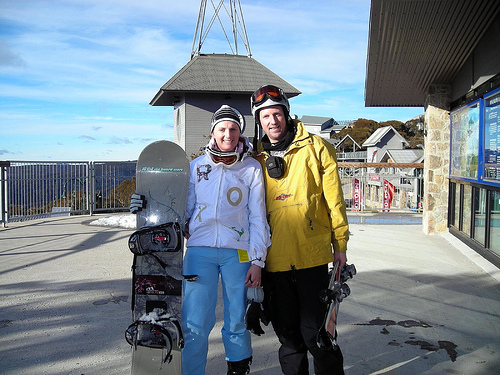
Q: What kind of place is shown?
A: It is a pavement.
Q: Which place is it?
A: It is a pavement.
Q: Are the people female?
A: No, they are both male and female.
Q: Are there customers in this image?
A: No, there are no customers.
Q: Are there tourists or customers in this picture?
A: No, there are no customers or tourists.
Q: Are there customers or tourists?
A: No, there are no customers or tourists.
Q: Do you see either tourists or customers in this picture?
A: No, there are no customers or tourists.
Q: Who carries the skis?
A: The man carries the skis.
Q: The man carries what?
A: The man carries skis.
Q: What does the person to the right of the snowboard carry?
A: The man carries skis.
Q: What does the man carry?
A: The man carries skis.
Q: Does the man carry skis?
A: Yes, the man carries skis.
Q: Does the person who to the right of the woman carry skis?
A: Yes, the man carries skis.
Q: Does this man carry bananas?
A: No, the man carries skis.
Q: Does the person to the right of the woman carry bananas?
A: No, the man carries skis.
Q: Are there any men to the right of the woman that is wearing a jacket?
A: Yes, there is a man to the right of the woman.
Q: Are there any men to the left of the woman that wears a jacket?
A: No, the man is to the right of the woman.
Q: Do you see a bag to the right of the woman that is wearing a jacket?
A: No, there is a man to the right of the woman.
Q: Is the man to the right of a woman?
A: Yes, the man is to the right of a woman.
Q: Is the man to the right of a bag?
A: No, the man is to the right of a woman.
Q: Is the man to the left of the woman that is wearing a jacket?
A: No, the man is to the right of the woman.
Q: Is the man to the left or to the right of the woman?
A: The man is to the right of the woman.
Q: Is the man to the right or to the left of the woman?
A: The man is to the right of the woman.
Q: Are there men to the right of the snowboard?
A: Yes, there is a man to the right of the snowboard.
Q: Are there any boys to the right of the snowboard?
A: No, there is a man to the right of the snowboard.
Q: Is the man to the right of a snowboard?
A: Yes, the man is to the right of a snowboard.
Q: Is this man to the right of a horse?
A: No, the man is to the right of a snowboard.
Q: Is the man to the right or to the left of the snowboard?
A: The man is to the right of the snowboard.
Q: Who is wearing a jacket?
A: The man is wearing a jacket.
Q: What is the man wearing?
A: The man is wearing a jacket.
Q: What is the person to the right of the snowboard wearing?
A: The man is wearing a jacket.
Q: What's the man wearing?
A: The man is wearing a jacket.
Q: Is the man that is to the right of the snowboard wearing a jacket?
A: Yes, the man is wearing a jacket.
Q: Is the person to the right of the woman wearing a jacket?
A: Yes, the man is wearing a jacket.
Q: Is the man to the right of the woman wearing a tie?
A: No, the man is wearing a jacket.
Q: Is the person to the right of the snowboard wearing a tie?
A: No, the man is wearing a jacket.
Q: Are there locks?
A: No, there are no locks.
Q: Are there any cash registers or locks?
A: No, there are no locks or cash registers.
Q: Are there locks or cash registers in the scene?
A: No, there are no locks or cash registers.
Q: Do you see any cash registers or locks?
A: No, there are no locks or cash registers.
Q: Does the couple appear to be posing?
A: Yes, the couple is posing.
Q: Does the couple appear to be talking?
A: No, the couple is posing.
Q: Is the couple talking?
A: No, the couple is posing.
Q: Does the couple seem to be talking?
A: No, the couple is posing.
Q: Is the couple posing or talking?
A: The couple is posing.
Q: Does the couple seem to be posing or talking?
A: The couple is posing.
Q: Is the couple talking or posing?
A: The couple is posing.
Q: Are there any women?
A: Yes, there is a woman.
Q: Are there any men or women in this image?
A: Yes, there is a woman.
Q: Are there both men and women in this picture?
A: Yes, there are both a woman and a man.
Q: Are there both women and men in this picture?
A: Yes, there are both a woman and a man.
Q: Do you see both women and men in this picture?
A: Yes, there are both a woman and a man.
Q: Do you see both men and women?
A: Yes, there are both a woman and a man.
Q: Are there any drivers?
A: No, there are no drivers.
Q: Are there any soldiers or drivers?
A: No, there are no drivers or soldiers.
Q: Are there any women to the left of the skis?
A: Yes, there is a woman to the left of the skis.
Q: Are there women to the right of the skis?
A: No, the woman is to the left of the skis.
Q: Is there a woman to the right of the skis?
A: No, the woman is to the left of the skis.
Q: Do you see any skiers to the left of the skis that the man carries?
A: No, there is a woman to the left of the skis.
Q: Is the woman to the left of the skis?
A: Yes, the woman is to the left of the skis.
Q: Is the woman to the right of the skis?
A: No, the woman is to the left of the skis.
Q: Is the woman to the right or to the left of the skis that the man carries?
A: The woman is to the left of the skis.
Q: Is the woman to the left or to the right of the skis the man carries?
A: The woman is to the left of the skis.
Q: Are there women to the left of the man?
A: Yes, there is a woman to the left of the man.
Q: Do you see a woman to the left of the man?
A: Yes, there is a woman to the left of the man.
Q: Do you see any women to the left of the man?
A: Yes, there is a woman to the left of the man.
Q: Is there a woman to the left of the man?
A: Yes, there is a woman to the left of the man.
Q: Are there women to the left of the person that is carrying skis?
A: Yes, there is a woman to the left of the man.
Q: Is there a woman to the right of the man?
A: No, the woman is to the left of the man.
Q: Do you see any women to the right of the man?
A: No, the woman is to the left of the man.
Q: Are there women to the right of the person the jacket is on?
A: No, the woman is to the left of the man.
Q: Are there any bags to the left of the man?
A: No, there is a woman to the left of the man.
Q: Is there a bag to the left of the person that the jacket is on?
A: No, there is a woman to the left of the man.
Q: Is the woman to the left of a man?
A: Yes, the woman is to the left of a man.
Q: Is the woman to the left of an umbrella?
A: No, the woman is to the left of a man.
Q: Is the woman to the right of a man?
A: No, the woman is to the left of a man.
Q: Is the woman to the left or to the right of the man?
A: The woman is to the left of the man.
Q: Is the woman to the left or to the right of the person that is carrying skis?
A: The woman is to the left of the man.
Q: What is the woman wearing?
A: The woman is wearing a jacket.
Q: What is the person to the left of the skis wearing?
A: The woman is wearing a jacket.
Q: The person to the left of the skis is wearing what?
A: The woman is wearing a jacket.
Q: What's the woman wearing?
A: The woman is wearing a jacket.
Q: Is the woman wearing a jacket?
A: Yes, the woman is wearing a jacket.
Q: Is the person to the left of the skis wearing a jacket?
A: Yes, the woman is wearing a jacket.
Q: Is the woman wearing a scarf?
A: No, the woman is wearing a jacket.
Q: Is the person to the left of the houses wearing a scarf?
A: No, the woman is wearing a jacket.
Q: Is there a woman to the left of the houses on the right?
A: Yes, there is a woman to the left of the houses.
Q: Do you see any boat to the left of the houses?
A: No, there is a woman to the left of the houses.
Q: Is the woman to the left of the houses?
A: Yes, the woman is to the left of the houses.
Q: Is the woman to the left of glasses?
A: No, the woman is to the left of the houses.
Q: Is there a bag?
A: No, there are no bags.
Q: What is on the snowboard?
A: The glove is on the snowboard.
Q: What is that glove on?
A: The glove is on the snowboard.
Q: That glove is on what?
A: The glove is on the snowboard.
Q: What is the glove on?
A: The glove is on the snowboard.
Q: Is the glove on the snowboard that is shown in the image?
A: Yes, the glove is on the snowboard.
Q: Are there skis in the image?
A: Yes, there are skis.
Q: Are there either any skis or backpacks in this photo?
A: Yes, there are skis.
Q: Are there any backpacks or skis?
A: Yes, there are skis.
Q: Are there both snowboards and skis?
A: Yes, there are both skis and a snowboard.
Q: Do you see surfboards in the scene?
A: No, there are no surfboards.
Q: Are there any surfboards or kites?
A: No, there are no surfboards or kites.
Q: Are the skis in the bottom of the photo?
A: Yes, the skis are in the bottom of the image.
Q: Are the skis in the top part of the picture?
A: No, the skis are in the bottom of the image.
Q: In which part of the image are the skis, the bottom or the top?
A: The skis are in the bottom of the image.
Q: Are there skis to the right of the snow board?
A: Yes, there are skis to the right of the snow board.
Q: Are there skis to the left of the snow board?
A: No, the skis are to the right of the snow board.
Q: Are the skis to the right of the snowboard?
A: Yes, the skis are to the right of the snowboard.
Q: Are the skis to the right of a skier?
A: No, the skis are to the right of the snowboard.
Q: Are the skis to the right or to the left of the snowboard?
A: The skis are to the right of the snowboard.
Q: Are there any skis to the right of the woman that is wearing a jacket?
A: Yes, there are skis to the right of the woman.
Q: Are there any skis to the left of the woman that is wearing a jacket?
A: No, the skis are to the right of the woman.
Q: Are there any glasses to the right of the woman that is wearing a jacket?
A: No, there are skis to the right of the woman.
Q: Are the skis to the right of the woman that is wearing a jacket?
A: Yes, the skis are to the right of the woman.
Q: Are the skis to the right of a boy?
A: No, the skis are to the right of the woman.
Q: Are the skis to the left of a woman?
A: No, the skis are to the right of a woman.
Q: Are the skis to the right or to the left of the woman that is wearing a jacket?
A: The skis are to the right of the woman.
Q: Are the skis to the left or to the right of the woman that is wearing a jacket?
A: The skis are to the right of the woman.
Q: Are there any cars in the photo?
A: No, there are no cars.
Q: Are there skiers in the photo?
A: No, there are no skiers.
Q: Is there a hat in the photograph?
A: Yes, there is a hat.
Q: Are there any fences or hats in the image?
A: Yes, there is a hat.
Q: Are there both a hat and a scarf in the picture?
A: No, there is a hat but no scarves.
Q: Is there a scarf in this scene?
A: No, there are no scarves.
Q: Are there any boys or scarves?
A: No, there are no scarves or boys.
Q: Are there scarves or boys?
A: No, there are no scarves or boys.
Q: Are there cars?
A: No, there are no cars.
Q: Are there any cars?
A: No, there are no cars.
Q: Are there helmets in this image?
A: Yes, there is a helmet.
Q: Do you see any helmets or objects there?
A: Yes, there is a helmet.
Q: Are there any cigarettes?
A: No, there are no cigarettes.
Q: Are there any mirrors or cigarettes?
A: No, there are no cigarettes or mirrors.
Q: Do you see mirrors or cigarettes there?
A: No, there are no cigarettes or mirrors.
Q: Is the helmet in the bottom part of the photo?
A: No, the helmet is in the top of the image.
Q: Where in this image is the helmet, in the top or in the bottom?
A: The helmet is in the top of the image.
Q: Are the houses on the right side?
A: Yes, the houses are on the right of the image.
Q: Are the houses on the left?
A: No, the houses are on the right of the image.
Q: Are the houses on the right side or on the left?
A: The houses are on the right of the image.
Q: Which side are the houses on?
A: The houses are on the right of the image.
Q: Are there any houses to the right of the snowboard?
A: Yes, there are houses to the right of the snowboard.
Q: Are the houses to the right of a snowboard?
A: Yes, the houses are to the right of a snowboard.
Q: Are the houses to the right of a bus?
A: No, the houses are to the right of a snowboard.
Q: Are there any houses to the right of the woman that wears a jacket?
A: Yes, there are houses to the right of the woman.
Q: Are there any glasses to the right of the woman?
A: No, there are houses to the right of the woman.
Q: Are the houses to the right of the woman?
A: Yes, the houses are to the right of the woman.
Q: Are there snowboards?
A: Yes, there is a snowboard.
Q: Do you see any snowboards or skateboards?
A: Yes, there is a snowboard.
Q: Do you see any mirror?
A: No, there are no mirrors.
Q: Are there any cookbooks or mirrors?
A: No, there are no mirrors or cookbooks.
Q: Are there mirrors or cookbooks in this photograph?
A: No, there are no mirrors or cookbooks.